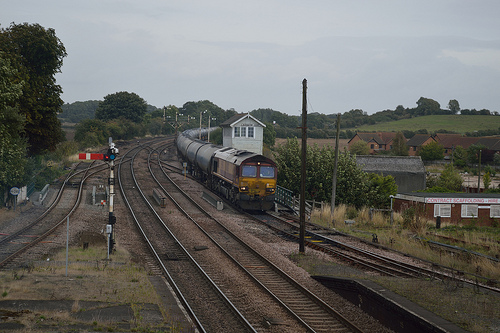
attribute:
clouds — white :
[39, 2, 498, 104]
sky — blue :
[2, 2, 497, 114]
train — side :
[177, 125, 278, 212]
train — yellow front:
[208, 142, 285, 213]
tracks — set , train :
[153, 189, 345, 319]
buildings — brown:
[338, 124, 498, 171]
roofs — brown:
[337, 122, 499, 155]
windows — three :
[233, 126, 257, 138]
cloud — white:
[57, 25, 499, 117]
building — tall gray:
[217, 107, 269, 159]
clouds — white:
[310, 30, 380, 65]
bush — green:
[282, 145, 375, 185]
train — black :
[171, 121, 281, 213]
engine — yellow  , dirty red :
[224, 153, 272, 213]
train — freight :
[173, 113, 209, 178]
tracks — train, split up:
[15, 134, 172, 286]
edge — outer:
[46, 127, 152, 203]